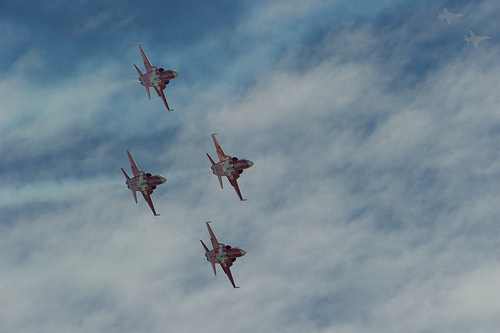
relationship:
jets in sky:
[120, 43, 253, 289] [0, 0, 499, 332]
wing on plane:
[219, 265, 241, 292] [182, 209, 268, 296]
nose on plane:
[239, 152, 255, 170] [197, 217, 248, 291]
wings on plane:
[211, 130, 246, 206] [165, 137, 290, 192]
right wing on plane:
[145, 195, 160, 216] [119, 145, 166, 217]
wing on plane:
[118, 144, 146, 172] [126, 37, 196, 113]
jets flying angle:
[121, 44, 254, 289] [118, 39, 250, 291]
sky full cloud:
[0, 0, 499, 332] [230, 80, 359, 142]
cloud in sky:
[0, 0, 499, 333] [0, 0, 499, 332]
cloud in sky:
[275, 64, 484, 191] [0, 0, 499, 332]